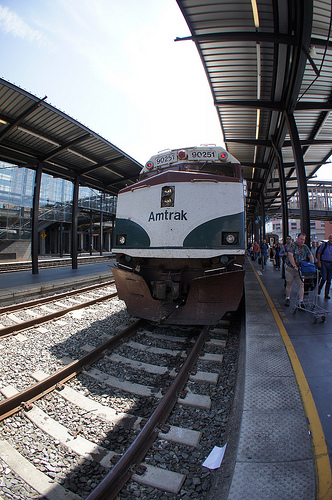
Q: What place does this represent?
A: It represents the train station.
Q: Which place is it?
A: It is a train station.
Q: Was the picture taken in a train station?
A: Yes, it was taken in a train station.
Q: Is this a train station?
A: Yes, it is a train station.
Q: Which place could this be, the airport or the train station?
A: It is the train station.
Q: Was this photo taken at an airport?
A: No, the picture was taken in a train station.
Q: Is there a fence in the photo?
A: No, there are no fences.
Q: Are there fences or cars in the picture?
A: No, there are no fences or cars.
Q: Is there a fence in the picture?
A: No, there are no fences.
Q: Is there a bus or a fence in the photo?
A: No, there are no fences or buses.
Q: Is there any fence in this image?
A: No, there are no fences.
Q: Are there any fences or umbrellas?
A: No, there are no fences or umbrellas.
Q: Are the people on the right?
A: Yes, the people are on the right of the image.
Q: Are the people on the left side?
A: No, the people are on the right of the image.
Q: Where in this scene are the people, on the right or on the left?
A: The people are on the right of the image.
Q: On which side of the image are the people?
A: The people are on the right of the image.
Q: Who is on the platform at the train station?
A: The people are on the platform.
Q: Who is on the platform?
A: The people are on the platform.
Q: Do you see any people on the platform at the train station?
A: Yes, there are people on the platform.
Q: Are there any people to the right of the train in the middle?
A: Yes, there are people to the right of the train.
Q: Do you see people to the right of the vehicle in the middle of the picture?
A: Yes, there are people to the right of the train.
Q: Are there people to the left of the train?
A: No, the people are to the right of the train.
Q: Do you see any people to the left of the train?
A: No, the people are to the right of the train.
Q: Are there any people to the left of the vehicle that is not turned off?
A: No, the people are to the right of the train.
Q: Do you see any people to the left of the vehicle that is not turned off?
A: No, the people are to the right of the train.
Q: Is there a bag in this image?
A: Yes, there is a bag.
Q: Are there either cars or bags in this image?
A: Yes, there is a bag.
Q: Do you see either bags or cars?
A: Yes, there is a bag.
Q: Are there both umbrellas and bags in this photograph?
A: No, there is a bag but no umbrellas.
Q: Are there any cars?
A: No, there are no cars.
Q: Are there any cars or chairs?
A: No, there are no cars or chairs.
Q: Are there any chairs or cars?
A: No, there are no cars or chairs.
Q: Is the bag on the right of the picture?
A: Yes, the bag is on the right of the image.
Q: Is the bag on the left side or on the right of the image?
A: The bag is on the right of the image.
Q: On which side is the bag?
A: The bag is on the right of the image.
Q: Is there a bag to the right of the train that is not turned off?
A: Yes, there is a bag to the right of the train.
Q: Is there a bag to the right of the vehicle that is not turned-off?
A: Yes, there is a bag to the right of the train.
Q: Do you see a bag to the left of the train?
A: No, the bag is to the right of the train.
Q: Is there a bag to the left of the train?
A: No, the bag is to the right of the train.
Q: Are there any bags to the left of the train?
A: No, the bag is to the right of the train.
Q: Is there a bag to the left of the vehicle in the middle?
A: No, the bag is to the right of the train.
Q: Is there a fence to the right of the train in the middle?
A: No, there is a bag to the right of the train.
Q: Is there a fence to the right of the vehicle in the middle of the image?
A: No, there is a bag to the right of the train.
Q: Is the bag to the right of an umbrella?
A: No, the bag is to the right of the train.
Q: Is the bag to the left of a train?
A: No, the bag is to the right of a train.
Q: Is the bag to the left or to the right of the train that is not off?
A: The bag is to the right of the train.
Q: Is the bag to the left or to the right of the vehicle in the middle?
A: The bag is to the right of the train.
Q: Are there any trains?
A: Yes, there is a train.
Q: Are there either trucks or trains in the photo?
A: Yes, there is a train.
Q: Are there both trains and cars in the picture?
A: No, there is a train but no cars.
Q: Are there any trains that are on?
A: Yes, there is a train that is on.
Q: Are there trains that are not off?
A: Yes, there is a train that is on.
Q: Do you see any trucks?
A: No, there are no trucks.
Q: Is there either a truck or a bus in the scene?
A: No, there are no trucks or buses.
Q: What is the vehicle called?
A: The vehicle is a train.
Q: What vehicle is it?
A: The vehicle is a train.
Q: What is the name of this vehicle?
A: This is a train.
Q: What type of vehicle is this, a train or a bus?
A: This is a train.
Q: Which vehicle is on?
A: The vehicle is a train.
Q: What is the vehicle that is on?
A: The vehicle is a train.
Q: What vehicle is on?
A: The vehicle is a train.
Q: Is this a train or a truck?
A: This is a train.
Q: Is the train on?
A: Yes, the train is on.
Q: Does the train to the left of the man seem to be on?
A: Yes, the train is on.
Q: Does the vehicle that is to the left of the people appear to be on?
A: Yes, the train is on.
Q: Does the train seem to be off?
A: No, the train is on.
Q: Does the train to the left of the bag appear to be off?
A: No, the train is on.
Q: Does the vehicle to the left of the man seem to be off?
A: No, the train is on.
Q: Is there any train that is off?
A: No, there is a train but it is on.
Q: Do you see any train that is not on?
A: No, there is a train but it is on.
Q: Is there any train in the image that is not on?
A: No, there is a train but it is on.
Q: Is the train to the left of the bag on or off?
A: The train is on.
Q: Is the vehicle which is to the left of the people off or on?
A: The train is on.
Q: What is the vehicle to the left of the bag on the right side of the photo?
A: The vehicle is a train.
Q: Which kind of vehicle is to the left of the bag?
A: The vehicle is a train.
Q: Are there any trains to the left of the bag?
A: Yes, there is a train to the left of the bag.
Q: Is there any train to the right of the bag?
A: No, the train is to the left of the bag.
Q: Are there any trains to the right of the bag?
A: No, the train is to the left of the bag.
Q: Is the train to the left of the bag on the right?
A: Yes, the train is to the left of the bag.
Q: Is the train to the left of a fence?
A: No, the train is to the left of the bag.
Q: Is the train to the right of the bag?
A: No, the train is to the left of the bag.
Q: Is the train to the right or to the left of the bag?
A: The train is to the left of the bag.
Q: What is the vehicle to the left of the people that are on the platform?
A: The vehicle is a train.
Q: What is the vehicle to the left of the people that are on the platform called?
A: The vehicle is a train.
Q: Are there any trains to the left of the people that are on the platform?
A: Yes, there is a train to the left of the people.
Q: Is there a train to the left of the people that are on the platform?
A: Yes, there is a train to the left of the people.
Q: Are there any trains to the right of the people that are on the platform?
A: No, the train is to the left of the people.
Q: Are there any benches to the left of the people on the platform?
A: No, there is a train to the left of the people.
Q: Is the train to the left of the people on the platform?
A: Yes, the train is to the left of the people.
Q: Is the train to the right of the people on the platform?
A: No, the train is to the left of the people.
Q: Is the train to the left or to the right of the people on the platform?
A: The train is to the left of the people.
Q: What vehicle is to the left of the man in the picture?
A: The vehicle is a train.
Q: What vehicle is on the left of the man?
A: The vehicle is a train.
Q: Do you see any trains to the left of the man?
A: Yes, there is a train to the left of the man.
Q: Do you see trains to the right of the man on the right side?
A: No, the train is to the left of the man.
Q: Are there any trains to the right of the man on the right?
A: No, the train is to the left of the man.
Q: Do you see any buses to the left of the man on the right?
A: No, there is a train to the left of the man.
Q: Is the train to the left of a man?
A: Yes, the train is to the left of a man.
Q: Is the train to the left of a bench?
A: No, the train is to the left of a man.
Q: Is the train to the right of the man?
A: No, the train is to the left of the man.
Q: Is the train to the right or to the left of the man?
A: The train is to the left of the man.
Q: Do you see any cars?
A: No, there are no cars.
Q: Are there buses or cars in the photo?
A: No, there are no cars or buses.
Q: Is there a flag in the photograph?
A: No, there are no flags.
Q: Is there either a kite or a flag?
A: No, there are no flags or kites.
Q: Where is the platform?
A: The platform is at the train station.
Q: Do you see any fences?
A: No, there are no fences.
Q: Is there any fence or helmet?
A: No, there are no fences or helmets.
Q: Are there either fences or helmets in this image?
A: No, there are no fences or helmets.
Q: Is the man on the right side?
A: Yes, the man is on the right of the image.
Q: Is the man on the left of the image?
A: No, the man is on the right of the image.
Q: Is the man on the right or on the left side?
A: The man is on the right of the image.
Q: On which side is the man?
A: The man is on the right of the image.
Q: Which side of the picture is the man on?
A: The man is on the right of the image.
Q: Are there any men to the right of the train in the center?
A: Yes, there is a man to the right of the train.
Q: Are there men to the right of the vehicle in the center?
A: Yes, there is a man to the right of the train.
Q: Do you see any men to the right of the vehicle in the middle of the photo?
A: Yes, there is a man to the right of the train.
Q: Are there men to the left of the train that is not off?
A: No, the man is to the right of the train.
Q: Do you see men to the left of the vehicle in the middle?
A: No, the man is to the right of the train.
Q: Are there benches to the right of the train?
A: No, there is a man to the right of the train.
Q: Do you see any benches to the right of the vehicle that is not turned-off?
A: No, there is a man to the right of the train.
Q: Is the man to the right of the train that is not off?
A: Yes, the man is to the right of the train.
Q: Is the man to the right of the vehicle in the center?
A: Yes, the man is to the right of the train.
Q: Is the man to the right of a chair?
A: No, the man is to the right of the train.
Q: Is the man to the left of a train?
A: No, the man is to the right of a train.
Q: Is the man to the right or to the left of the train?
A: The man is to the right of the train.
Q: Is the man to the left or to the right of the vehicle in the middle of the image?
A: The man is to the right of the train.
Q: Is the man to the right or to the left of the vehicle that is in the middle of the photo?
A: The man is to the right of the train.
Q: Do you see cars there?
A: No, there are no cars.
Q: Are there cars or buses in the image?
A: No, there are no cars or buses.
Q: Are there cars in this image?
A: No, there are no cars.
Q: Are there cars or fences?
A: No, there are no cars or fences.